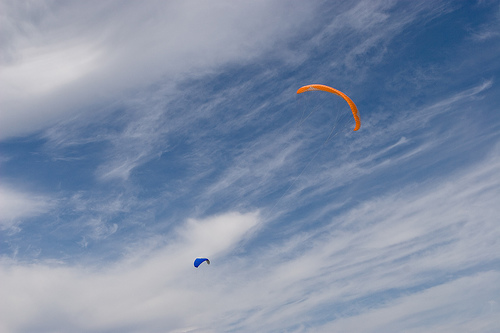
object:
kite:
[194, 257, 211, 268]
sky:
[0, 5, 496, 328]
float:
[194, 257, 211, 269]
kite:
[296, 83, 361, 132]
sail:
[193, 257, 210, 267]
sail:
[293, 84, 361, 132]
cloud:
[14, 264, 264, 332]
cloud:
[309, 264, 498, 331]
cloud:
[4, 180, 49, 215]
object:
[291, 80, 360, 132]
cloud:
[124, 209, 259, 282]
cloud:
[1, 0, 321, 145]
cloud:
[64, 190, 131, 248]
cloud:
[357, 82, 492, 155]